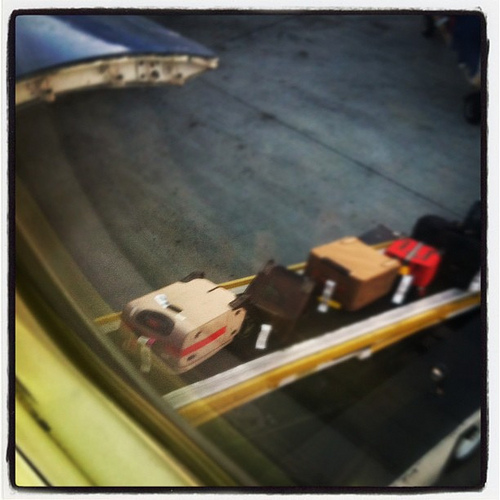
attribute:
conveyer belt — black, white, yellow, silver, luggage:
[94, 219, 468, 407]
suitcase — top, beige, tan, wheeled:
[119, 269, 243, 375]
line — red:
[167, 321, 228, 371]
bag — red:
[393, 237, 432, 281]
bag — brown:
[247, 255, 308, 335]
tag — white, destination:
[131, 334, 164, 379]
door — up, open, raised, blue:
[1, 22, 233, 107]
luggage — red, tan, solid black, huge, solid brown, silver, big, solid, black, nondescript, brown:
[90, 184, 487, 333]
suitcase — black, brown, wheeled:
[234, 264, 328, 336]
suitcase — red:
[395, 236, 450, 290]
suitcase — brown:
[318, 239, 414, 341]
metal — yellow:
[16, 331, 169, 482]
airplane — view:
[21, 28, 260, 478]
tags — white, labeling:
[133, 296, 453, 365]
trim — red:
[181, 332, 229, 355]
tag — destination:
[254, 324, 268, 350]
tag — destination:
[401, 272, 423, 300]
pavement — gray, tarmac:
[86, 37, 495, 235]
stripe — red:
[178, 314, 228, 346]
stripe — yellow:
[169, 299, 474, 418]